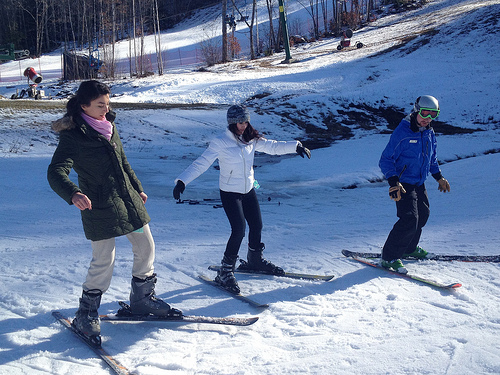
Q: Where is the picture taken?
A: A ski slope.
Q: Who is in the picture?
A: A man and two girls.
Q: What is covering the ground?
A: Snow.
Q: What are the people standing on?
A: Skis.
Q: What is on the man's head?
A: A helmet.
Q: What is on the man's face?
A: Goggles.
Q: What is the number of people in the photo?
A: Three.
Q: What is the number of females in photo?
A: Two.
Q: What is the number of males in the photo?
A: One.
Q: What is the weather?
A: Cold.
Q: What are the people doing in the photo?
A: Skiing.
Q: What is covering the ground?
A: Snow.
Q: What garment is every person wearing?
A: A coat.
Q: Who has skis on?
A: Two women and a man.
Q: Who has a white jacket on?
A: The woman in the middle.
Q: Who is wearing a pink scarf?
A: The woman on the left.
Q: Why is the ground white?
A: It's covered with snow.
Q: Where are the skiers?
A: On a ski slope.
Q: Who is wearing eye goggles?
A: The skier in the blue jacket.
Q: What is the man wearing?
A: Blue jacket and black pants.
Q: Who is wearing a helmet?
A: The man.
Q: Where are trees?
A: Behind the skiers.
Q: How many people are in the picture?
A: Three.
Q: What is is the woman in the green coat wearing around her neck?
A: A scarf.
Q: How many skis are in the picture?
A: 6.